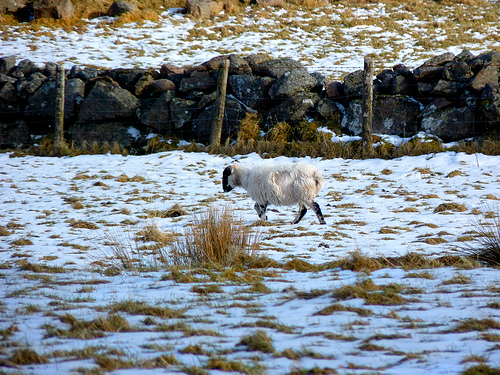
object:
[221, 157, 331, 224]
sheep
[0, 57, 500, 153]
wall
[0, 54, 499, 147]
fence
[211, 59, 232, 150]
post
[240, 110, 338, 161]
bush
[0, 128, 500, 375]
field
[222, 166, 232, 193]
face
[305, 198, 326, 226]
legs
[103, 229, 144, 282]
grass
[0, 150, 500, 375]
snow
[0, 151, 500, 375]
ground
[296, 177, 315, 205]
fur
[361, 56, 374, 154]
stakes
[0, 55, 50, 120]
rocks